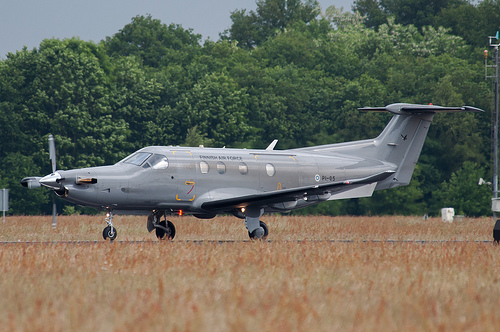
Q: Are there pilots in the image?
A: No, there are no pilots.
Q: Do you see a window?
A: Yes, there are windows.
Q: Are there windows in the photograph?
A: Yes, there are windows.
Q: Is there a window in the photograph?
A: Yes, there are windows.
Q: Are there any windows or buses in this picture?
A: Yes, there are windows.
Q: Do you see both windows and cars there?
A: No, there are windows but no cars.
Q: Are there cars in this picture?
A: No, there are no cars.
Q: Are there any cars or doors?
A: No, there are no cars or doors.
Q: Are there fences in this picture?
A: No, there are no fences.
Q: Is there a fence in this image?
A: No, there are no fences.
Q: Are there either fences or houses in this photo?
A: No, there are no fences or houses.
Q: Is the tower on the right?
A: Yes, the tower is on the right of the image.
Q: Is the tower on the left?
A: No, the tower is on the right of the image.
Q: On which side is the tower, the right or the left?
A: The tower is on the right of the image.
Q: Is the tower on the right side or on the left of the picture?
A: The tower is on the right of the image.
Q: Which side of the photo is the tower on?
A: The tower is on the right of the image.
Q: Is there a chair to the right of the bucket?
A: No, there is a tower to the right of the bucket.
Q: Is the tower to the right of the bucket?
A: Yes, the tower is to the right of the bucket.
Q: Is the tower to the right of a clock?
A: No, the tower is to the right of the bucket.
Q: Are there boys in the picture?
A: No, there are no boys.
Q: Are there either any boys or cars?
A: No, there are no boys or cars.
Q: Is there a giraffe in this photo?
A: No, there are no giraffes.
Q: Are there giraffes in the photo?
A: No, there are no giraffes.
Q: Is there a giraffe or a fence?
A: No, there are no giraffes or fences.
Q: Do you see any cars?
A: No, there are no cars.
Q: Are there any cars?
A: No, there are no cars.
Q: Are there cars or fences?
A: No, there are no cars or fences.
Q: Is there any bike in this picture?
A: No, there are no bikes.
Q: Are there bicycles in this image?
A: No, there are no bicycles.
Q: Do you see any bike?
A: No, there are no bikes.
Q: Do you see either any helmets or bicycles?
A: No, there are no bicycles or helmets.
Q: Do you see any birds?
A: No, there are no birds.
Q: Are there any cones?
A: No, there are no cones.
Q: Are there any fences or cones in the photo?
A: No, there are no cones or fences.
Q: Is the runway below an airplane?
A: Yes, the runway is below an airplane.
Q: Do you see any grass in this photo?
A: Yes, there is grass.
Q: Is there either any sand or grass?
A: Yes, there is grass.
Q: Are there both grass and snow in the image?
A: No, there is grass but no snow.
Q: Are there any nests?
A: No, there are no nests.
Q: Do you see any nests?
A: No, there are no nests.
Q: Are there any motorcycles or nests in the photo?
A: No, there are no nests or motorcycles.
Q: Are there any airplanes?
A: Yes, there is an airplane.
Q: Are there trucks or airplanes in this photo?
A: Yes, there is an airplane.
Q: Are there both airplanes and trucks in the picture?
A: No, there is an airplane but no trucks.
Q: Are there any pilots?
A: No, there are no pilots.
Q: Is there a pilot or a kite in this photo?
A: No, there are no pilots or kites.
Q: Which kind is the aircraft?
A: The aircraft is an airplane.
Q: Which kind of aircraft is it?
A: The aircraft is an airplane.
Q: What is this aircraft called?
A: This is an airplane.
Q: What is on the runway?
A: The airplane is on the runway.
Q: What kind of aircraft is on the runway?
A: The aircraft is an airplane.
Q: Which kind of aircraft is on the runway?
A: The aircraft is an airplane.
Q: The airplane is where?
A: The airplane is on the runway.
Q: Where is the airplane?
A: The airplane is on the runway.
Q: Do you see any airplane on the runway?
A: Yes, there is an airplane on the runway.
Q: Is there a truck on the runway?
A: No, there is an airplane on the runway.